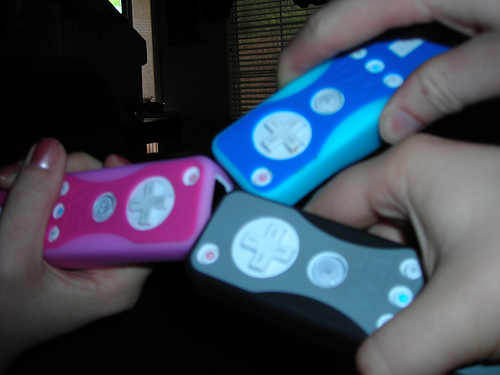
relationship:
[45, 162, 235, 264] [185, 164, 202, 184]
controller has button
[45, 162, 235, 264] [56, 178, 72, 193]
controller has button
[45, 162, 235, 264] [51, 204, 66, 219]
controller has button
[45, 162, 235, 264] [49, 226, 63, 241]
controller has button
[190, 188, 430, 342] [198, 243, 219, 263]
controller has button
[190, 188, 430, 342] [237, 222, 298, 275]
controller has button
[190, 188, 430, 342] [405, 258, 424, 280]
controller has button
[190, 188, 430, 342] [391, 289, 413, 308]
controller has button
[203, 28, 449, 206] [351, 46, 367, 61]
controller has button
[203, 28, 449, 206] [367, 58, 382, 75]
controller has button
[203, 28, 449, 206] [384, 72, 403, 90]
controller has button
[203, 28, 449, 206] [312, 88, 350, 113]
controller has button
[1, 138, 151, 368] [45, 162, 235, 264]
hand holding controller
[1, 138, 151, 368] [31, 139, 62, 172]
hand has pink nail polish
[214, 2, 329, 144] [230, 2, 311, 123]
window has blinds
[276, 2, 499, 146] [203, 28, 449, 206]
hand holding controller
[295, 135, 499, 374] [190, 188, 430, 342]
hand holding controller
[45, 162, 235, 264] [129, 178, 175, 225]
controller has button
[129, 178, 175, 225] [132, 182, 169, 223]
button has cross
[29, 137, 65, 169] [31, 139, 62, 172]
finger nail painted with pink nail polish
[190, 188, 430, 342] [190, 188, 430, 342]
controller on controller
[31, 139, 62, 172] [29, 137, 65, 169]
pink nail polish on finger nail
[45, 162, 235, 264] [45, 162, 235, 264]
controller on controller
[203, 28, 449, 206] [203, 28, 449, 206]
controller on controller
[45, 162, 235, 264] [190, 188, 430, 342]
controller touching controller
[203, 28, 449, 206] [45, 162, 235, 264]
controller touching controller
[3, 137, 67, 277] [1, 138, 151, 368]
thumb on hand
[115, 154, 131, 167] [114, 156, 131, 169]
finger nail has nail polish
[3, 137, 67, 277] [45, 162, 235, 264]
thumb on top of controller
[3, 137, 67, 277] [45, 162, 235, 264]
thumb on side of controller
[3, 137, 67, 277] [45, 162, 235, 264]
thumb wrapped around controller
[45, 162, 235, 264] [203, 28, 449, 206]
controller touching controller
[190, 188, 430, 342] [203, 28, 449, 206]
controller touching controller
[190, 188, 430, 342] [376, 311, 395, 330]
controller has button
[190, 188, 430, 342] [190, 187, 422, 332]
controller has surface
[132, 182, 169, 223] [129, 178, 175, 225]
cross over button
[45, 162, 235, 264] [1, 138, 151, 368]
controller in hand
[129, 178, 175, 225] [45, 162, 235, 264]
button in center of controller